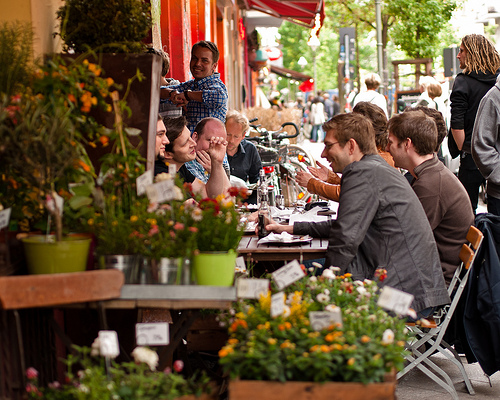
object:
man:
[161, 40, 232, 184]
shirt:
[161, 73, 231, 184]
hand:
[209, 136, 229, 161]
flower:
[228, 186, 241, 197]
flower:
[215, 193, 226, 202]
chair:
[397, 226, 484, 399]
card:
[271, 259, 306, 292]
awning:
[242, 0, 328, 30]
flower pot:
[17, 234, 94, 275]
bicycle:
[242, 118, 318, 200]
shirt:
[447, 69, 498, 162]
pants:
[458, 154, 500, 218]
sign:
[138, 323, 171, 346]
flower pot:
[190, 248, 236, 286]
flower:
[79, 92, 97, 113]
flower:
[84, 59, 104, 77]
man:
[254, 111, 452, 324]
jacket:
[447, 212, 499, 377]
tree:
[322, 0, 463, 103]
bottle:
[258, 193, 271, 237]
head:
[190, 40, 221, 79]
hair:
[321, 111, 378, 155]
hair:
[385, 112, 437, 157]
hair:
[403, 105, 447, 153]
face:
[190, 45, 213, 77]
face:
[174, 125, 198, 163]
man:
[164, 117, 238, 202]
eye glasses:
[324, 141, 349, 149]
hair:
[461, 34, 500, 75]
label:
[257, 213, 264, 235]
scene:
[0, 0, 499, 399]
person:
[310, 97, 327, 142]